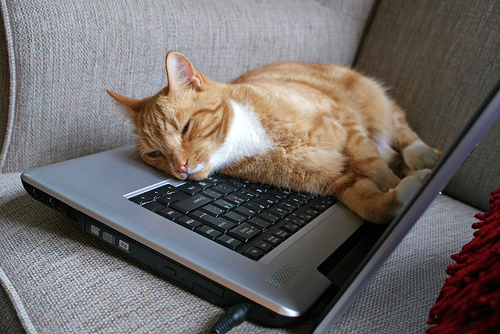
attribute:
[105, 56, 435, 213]
cat — white, brown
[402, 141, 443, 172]
paw — white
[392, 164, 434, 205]
paw — white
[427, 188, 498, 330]
fringe — red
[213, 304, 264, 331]
charger — laptop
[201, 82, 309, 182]
ruff — white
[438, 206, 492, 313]
pillow — red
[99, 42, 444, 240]
cat — comfortable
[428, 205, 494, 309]
pillow — red, fringe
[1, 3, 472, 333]
chair — gray